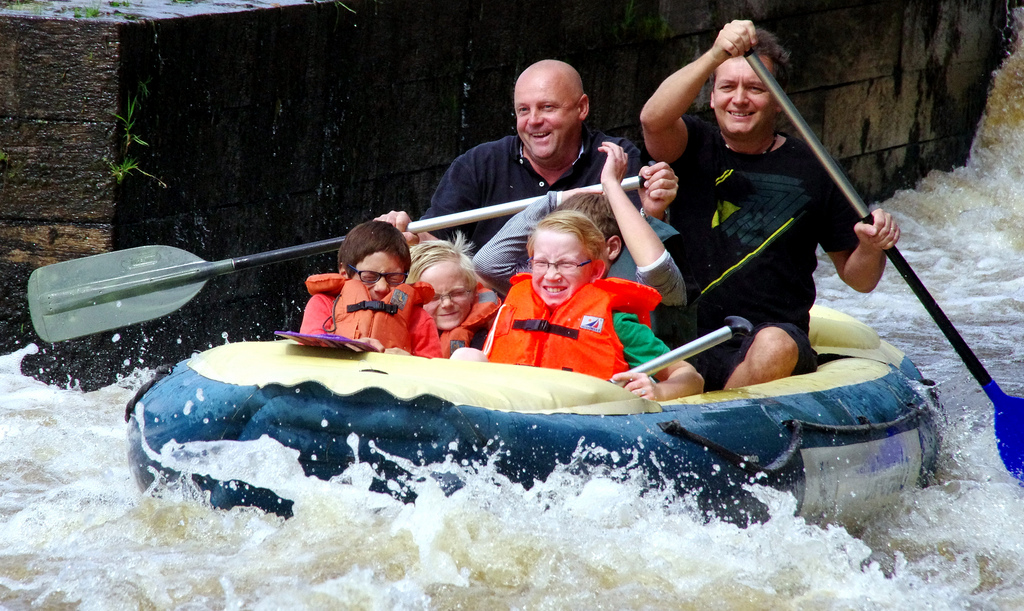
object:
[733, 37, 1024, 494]
paddle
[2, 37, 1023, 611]
water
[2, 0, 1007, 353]
wall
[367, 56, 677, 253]
person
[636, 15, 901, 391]
person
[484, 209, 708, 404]
boy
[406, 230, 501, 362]
boy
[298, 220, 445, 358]
boy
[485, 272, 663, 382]
vest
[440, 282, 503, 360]
vest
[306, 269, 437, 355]
vest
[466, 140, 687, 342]
girl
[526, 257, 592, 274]
glasses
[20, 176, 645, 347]
paddle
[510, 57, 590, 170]
part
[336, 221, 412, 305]
part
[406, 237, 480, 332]
part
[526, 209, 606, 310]
part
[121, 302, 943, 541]
raft